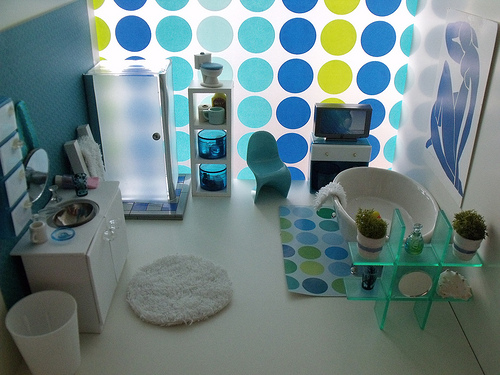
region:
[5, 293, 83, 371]
white trash bin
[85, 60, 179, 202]
small glass shower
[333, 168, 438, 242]
mini white bath tub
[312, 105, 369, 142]
tiny black tv on stand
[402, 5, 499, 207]
painting on wall over tub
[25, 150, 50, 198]
small circular mirror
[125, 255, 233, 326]
small, white fluffy bath rug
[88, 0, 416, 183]
polka dot glass wall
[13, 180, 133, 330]
white counter with sink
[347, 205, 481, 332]
green glass shelf with plants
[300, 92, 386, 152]
The TV is on.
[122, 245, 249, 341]
The rug is circular.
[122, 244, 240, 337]
The rug is white.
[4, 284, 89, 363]
The trash can is white.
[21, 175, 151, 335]
The vanity is white.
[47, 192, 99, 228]
The sink is silver.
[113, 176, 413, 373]
The floor is white.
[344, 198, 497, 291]
The plants are on the table.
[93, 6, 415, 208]
The wall is polka dotted.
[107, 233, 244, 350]
a small white rug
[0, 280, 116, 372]
a white trash can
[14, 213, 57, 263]
a white coffee mug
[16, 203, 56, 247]
a white coffee mug on a sink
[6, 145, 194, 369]
a white sink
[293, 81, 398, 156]
a small black tv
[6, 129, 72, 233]
a small circle mirror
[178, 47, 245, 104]
a small toilet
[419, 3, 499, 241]
a painting on the wall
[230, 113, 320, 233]
a small blue chair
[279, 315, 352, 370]
white floor of the bathroom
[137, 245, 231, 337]
round white rug on the floor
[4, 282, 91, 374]
white waste can on the floor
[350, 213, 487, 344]
green glass shelf next to the tub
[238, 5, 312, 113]
spotted glass wall of the bathroom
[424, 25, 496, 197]
blue and white portrait on the wall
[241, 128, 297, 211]
blue plastic chair on the floor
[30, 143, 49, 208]
small round mirror on the wall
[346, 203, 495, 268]
two potted plants on the shelf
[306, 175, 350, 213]
a white towel draped over the tub